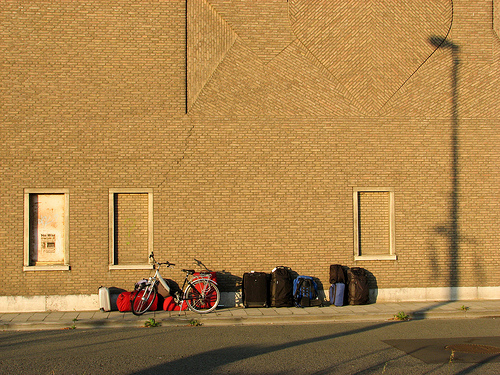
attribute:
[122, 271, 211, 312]
suitcases — red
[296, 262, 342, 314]
bags — blue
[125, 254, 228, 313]
bike — white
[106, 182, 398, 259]
windows — bricked, brown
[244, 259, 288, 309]
luggage — black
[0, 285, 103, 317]
base — white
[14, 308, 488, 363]
road — empty, grey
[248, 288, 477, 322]
sidewalk — cement, grey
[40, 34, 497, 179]
wall — grey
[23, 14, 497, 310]
building — large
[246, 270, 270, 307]
suitcases — black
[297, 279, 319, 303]
backpack — blue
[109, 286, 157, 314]
bag — red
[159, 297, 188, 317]
gym bag — red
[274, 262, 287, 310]
sleeping bag — black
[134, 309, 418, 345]
weeds — growing